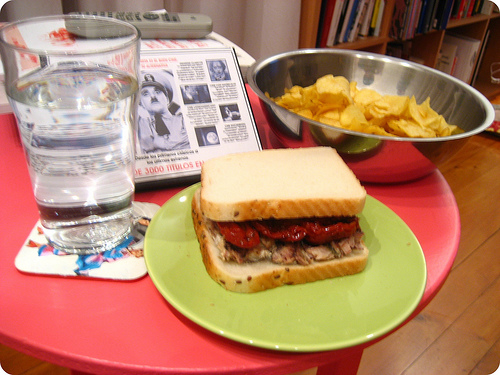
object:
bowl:
[249, 50, 494, 182]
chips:
[337, 104, 369, 127]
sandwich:
[193, 145, 368, 300]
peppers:
[263, 218, 307, 246]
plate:
[146, 180, 429, 353]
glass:
[0, 18, 143, 252]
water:
[12, 74, 129, 235]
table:
[2, 60, 466, 374]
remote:
[66, 4, 221, 38]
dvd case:
[79, 47, 266, 187]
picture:
[139, 67, 186, 150]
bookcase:
[302, 4, 499, 96]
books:
[320, 4, 330, 48]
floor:
[432, 299, 498, 373]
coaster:
[13, 198, 161, 282]